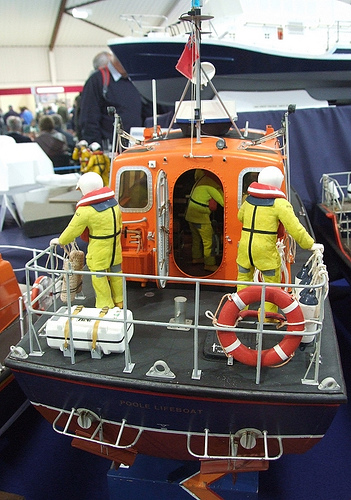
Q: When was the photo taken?
A: Daytime.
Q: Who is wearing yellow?
A: Three people.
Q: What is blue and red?
A: Boat.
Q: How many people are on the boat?
A: Three.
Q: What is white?
A: Helmets.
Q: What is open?
A: A door.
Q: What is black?
A: Floor of boat.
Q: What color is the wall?
A: White.